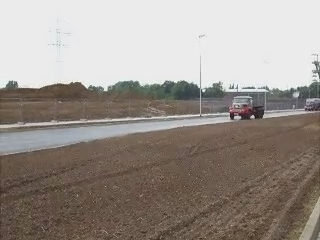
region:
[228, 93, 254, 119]
The truck in the background is red.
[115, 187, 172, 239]
The dirt in the forefront is brown.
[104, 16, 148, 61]
The sky is gray in color.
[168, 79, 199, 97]
The trees in the background are green.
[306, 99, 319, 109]
The truck in the distance is dark in color.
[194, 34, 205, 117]
The light pole is tall.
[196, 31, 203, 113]
The light pole is gray.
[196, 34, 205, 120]
The light pole is made of metal.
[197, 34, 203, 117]
The light pole is slender.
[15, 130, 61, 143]
The pavement is black.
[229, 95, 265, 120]
truck driving on a road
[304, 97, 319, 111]
truck behind truck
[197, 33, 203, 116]
pole next to road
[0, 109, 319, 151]
road beneath truck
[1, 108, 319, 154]
the road is smooth and gray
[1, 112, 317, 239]
brown dirt next to road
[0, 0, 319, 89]
sky above road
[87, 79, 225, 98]
green trees below sky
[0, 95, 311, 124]
metal fence beside road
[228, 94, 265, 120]
truck to the right of fence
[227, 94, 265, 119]
Truck on the road.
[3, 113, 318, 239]
Dirt covering the ground.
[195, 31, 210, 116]
Street light beside the road.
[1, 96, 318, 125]
Fence in the background.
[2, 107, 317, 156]
Paved road in the background.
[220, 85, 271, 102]
House in the background.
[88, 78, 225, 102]
Trees in the background.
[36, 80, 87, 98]
Dirt pile in the background.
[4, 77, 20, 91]
Building in the background.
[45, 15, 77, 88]
Power line tower in the background.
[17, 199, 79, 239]
PAtch of brown dirt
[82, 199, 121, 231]
PAtch of brown dirt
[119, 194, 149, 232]
PAtch of brown dirt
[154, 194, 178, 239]
PAtch of brown dirt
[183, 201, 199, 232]
PAtch of brown dirt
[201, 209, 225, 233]
PAtch of brown dirt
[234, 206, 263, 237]
PAtch of brown dirt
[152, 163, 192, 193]
PAtch of brown dirt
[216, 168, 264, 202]
PAtch of brown dirt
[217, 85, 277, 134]
Truck on the pavement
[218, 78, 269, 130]
a red tractor truck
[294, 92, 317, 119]
a semi truck coming into view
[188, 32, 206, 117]
a tall light pole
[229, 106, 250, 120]
red on the front of truck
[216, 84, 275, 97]
white top of a building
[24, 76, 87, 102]
a big dirt mound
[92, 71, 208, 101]
a line of trees in the distance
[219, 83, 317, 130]
two trucks on the road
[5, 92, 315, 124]
a fence along the road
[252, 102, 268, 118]
flat bed of truck